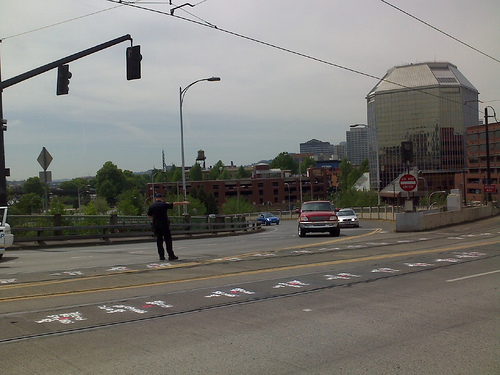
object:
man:
[146, 191, 178, 262]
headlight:
[300, 214, 309, 225]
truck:
[297, 200, 342, 238]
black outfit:
[146, 201, 176, 256]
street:
[0, 215, 500, 374]